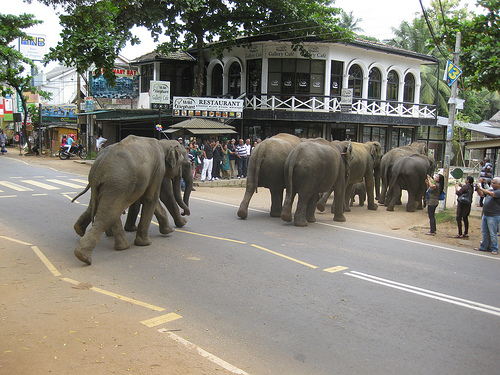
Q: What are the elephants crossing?
A: The street.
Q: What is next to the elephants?
A: The building.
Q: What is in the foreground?
A: Elephants.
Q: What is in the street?
A: Elephants.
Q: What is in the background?
A: The building.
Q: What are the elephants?
A: Gray.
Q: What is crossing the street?
A: The group of elephants.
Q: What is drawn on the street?
A: Double white lines.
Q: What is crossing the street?
A: The elephants.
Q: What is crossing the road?
A: Elephants.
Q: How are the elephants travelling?
A: Walking.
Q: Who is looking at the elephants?
A: Crowd of people.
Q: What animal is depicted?
A: Elephant.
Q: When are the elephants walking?
A: Now.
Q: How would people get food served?
A: At the restaurant on the corner.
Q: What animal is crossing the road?
A: Elephants.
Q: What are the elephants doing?
A: Walking across road.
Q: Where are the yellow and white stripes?
A: On road.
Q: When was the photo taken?
A: Daytime.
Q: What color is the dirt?
A: Brown.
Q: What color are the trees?
A: Green.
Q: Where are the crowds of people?
A: On sidewalk.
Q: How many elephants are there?
A: 7.